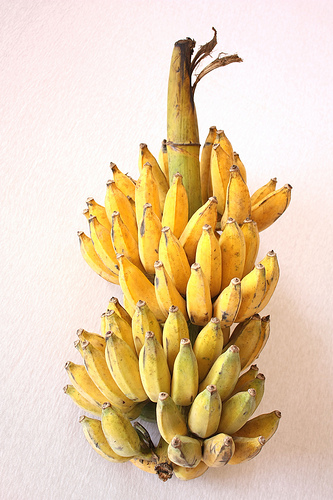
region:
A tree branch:
[153, 24, 241, 214]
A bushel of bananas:
[62, 125, 293, 480]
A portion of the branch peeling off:
[191, 27, 241, 103]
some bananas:
[62, 120, 292, 463]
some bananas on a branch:
[62, 120, 291, 482]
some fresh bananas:
[60, 125, 295, 489]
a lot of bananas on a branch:
[63, 116, 292, 490]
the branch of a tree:
[152, 26, 241, 215]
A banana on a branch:
[219, 163, 254, 224]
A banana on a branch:
[161, 172, 191, 238]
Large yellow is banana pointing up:
[159, 227, 191, 299]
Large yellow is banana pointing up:
[195, 220, 224, 294]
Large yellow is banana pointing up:
[133, 194, 161, 271]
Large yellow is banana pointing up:
[88, 210, 118, 276]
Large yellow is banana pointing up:
[112, 246, 159, 316]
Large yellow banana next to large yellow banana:
[161, 303, 187, 363]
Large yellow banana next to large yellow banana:
[181, 257, 207, 318]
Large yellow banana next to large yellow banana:
[218, 215, 240, 286]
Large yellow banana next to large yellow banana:
[212, 139, 234, 213]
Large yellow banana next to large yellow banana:
[74, 228, 119, 286]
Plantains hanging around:
[75, 25, 302, 479]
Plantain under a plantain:
[131, 298, 173, 402]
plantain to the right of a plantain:
[225, 164, 293, 235]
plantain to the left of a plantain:
[222, 165, 293, 230]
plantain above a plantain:
[188, 341, 243, 437]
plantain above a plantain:
[125, 300, 171, 402]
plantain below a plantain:
[129, 303, 172, 401]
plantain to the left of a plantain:
[74, 331, 143, 406]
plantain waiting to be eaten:
[58, 26, 298, 483]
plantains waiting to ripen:
[56, 26, 293, 486]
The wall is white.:
[13, 13, 141, 125]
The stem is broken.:
[167, 22, 231, 94]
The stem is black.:
[172, 31, 199, 79]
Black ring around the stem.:
[158, 130, 197, 153]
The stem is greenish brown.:
[163, 70, 201, 179]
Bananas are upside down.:
[74, 88, 298, 494]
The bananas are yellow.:
[121, 307, 241, 434]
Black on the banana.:
[134, 195, 156, 243]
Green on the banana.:
[175, 347, 200, 376]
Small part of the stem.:
[150, 458, 174, 487]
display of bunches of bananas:
[59, 23, 293, 480]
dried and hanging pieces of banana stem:
[162, 22, 242, 104]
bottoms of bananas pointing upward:
[113, 166, 256, 453]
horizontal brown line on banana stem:
[162, 118, 197, 168]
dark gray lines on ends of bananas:
[101, 201, 175, 249]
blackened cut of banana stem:
[170, 34, 189, 43]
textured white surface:
[2, 7, 109, 129]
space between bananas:
[125, 404, 157, 451]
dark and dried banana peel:
[129, 419, 149, 451]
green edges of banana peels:
[175, 338, 237, 366]